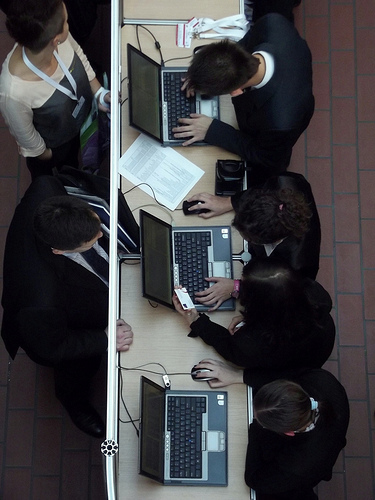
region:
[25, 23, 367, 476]
people sitting down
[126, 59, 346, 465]
people on their laptops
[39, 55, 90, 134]
a woman wears a tag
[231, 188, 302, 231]
a woman has long hair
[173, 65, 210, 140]
a man is typing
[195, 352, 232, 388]
a person has the hand on the mouse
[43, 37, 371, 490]
picture taken from above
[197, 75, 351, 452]
the tops of people's heads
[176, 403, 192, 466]
the keyboard is black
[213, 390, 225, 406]
stickers on the laptop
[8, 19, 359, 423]
This is a group of people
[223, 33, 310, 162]
This man is wearing a suit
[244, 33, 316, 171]
The man's jacket is black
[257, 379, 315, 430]
This person has brown hair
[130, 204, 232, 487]
These are laptops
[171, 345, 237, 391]
The hand is on the mouse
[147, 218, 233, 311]
These laptops are gray and dark gray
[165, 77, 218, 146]
The man is typing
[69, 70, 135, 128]
She has something on her hand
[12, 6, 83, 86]
Her hair is brown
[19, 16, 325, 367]
These people are studying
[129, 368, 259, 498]
This is a laptop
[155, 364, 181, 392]
The laptop is locked down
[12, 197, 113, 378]
The man is wearing a suit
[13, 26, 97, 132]
this person has a necklace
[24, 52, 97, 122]
The necklace is white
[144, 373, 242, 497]
The laptop is black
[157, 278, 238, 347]
The girl is holding a card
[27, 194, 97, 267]
The man has short hair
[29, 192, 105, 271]
The man's hair is brown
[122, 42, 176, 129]
this is a laptop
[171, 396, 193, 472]
these are the buttons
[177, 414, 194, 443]
the buttons are black in color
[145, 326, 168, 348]
this is a table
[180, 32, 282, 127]
this is a man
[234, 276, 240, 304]
this is a wrist watch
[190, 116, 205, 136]
the man is light skinned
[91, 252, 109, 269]
this is a neck tie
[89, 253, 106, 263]
the neck tie is black in color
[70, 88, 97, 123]
this is a berg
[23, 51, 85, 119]
A white band around the womens neck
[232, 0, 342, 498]
The row of people dressed in black suits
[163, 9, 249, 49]
Tags for people to wear around their necks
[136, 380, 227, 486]
A black laptop computer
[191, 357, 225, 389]
The hand on the computers mouse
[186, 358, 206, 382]
The black paint on the fingernails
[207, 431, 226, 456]
The mouse pad on the laptop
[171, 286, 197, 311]
The card in the womens hand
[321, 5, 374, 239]
The red brick floor with lines in it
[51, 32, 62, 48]
An earring in the womens right ear